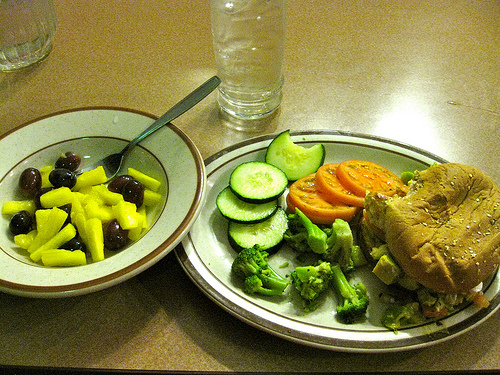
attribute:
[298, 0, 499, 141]
table — brown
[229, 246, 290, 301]
broccoli — cut, green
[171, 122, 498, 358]
plate — white, healthy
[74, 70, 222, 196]
spoon — metallic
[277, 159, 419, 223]
tomatoes — slices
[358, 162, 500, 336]
hamburger — brown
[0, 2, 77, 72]
jug — clear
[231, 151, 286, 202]
cucumber — sliced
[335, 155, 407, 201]
tomatoe — red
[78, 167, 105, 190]
pineapple — cut, sliced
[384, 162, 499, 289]
bun — smashed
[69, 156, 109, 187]
pineapples — chunks